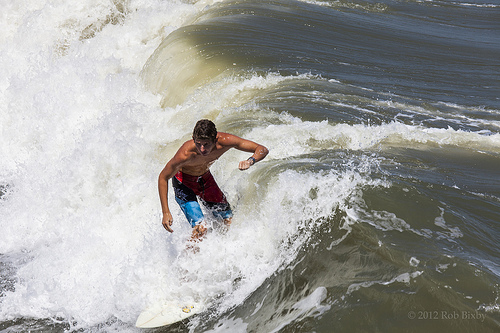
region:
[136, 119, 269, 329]
Young man surfing wave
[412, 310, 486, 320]
Photo credits in the corner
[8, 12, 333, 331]
White of crashing wave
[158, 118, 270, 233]
Young man in swimsuit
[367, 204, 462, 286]
Foam on seawater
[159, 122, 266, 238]
Sunburn on guy's shoulder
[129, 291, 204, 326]
Surfboard peeking through waves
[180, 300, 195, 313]
Small design on surfboard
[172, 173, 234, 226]
Red and blue men's swimsuit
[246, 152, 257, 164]
Surfboard leash on wrist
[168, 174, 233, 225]
red and blue trunks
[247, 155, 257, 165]
black watch on wrist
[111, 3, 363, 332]
wave breaking in ocean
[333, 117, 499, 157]
white foam in ocean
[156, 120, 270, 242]
man standing on surf board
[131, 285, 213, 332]
long white surf board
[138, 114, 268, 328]
man surfing in ocean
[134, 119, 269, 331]
man surfing on wave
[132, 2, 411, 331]
wave formed in ocean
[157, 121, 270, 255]
man with no shirt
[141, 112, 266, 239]
a person surfing in the ocean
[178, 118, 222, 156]
the head of a young man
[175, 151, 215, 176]
the torso of a young man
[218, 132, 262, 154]
the arm of a young man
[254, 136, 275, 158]
the elbow of a young man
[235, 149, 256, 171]
the hand of a young man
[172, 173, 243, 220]
the swim shorts of a young man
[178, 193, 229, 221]
the thighs of a young man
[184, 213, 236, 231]
the knees of a young man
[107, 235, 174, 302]
the foam of some waves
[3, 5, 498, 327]
surface of ocean water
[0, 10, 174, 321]
white water of crashed wave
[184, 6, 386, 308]
swell of ocean wave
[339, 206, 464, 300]
sea foam on surface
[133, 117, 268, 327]
man on top of surfboard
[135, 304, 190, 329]
tip of white board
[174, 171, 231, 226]
shorts on man's body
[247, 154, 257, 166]
watch on man's wrist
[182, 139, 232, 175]
bare chest of man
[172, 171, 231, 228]
red and blue shorts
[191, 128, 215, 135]
Person has short hair.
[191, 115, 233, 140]
Person has brown hair.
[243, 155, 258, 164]
Band around person's wrist.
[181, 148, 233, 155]
Person is bare chested.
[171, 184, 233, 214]
Person wearing shorts.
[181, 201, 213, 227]
Blue coloring on shorts.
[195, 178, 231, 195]
Red coloring on shorts.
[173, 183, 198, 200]
Dark black coloring on shorts.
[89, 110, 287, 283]
Person is in water.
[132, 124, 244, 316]
Person is surfing in water.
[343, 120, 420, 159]
A wave in the water.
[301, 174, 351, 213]
A wave in the water.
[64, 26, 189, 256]
A wave in the water.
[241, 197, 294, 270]
A wave in the water.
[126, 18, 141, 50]
A wave in the water.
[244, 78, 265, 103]
A wave in the water.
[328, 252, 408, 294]
A wave in the water.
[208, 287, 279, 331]
A wave in the water.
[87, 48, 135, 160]
A wave in the water.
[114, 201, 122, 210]
A white foam of water.